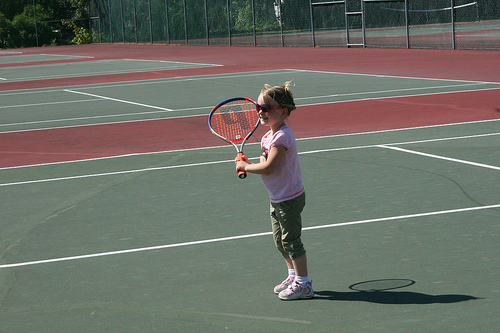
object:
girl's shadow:
[312, 289, 481, 305]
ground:
[0, 46, 499, 333]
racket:
[206, 97, 263, 179]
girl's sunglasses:
[255, 103, 284, 112]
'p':
[218, 104, 250, 132]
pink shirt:
[259, 125, 305, 204]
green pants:
[268, 189, 307, 259]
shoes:
[277, 281, 315, 301]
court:
[0, 1, 500, 333]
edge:
[269, 186, 305, 204]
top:
[206, 96, 259, 118]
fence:
[33, 0, 500, 51]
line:
[0, 203, 500, 268]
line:
[375, 144, 500, 171]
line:
[0, 132, 500, 187]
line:
[63, 88, 174, 112]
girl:
[234, 78, 316, 300]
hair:
[259, 77, 296, 118]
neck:
[270, 120, 287, 136]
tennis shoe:
[273, 274, 296, 295]